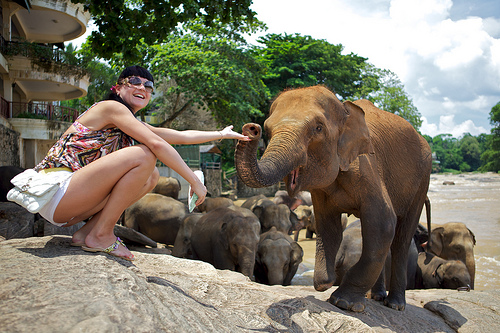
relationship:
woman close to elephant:
[8, 66, 251, 262] [235, 83, 435, 313]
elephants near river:
[121, 176, 478, 290] [414, 170, 497, 291]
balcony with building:
[0, 1, 92, 172] [4, 41, 91, 102]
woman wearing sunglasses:
[8, 66, 251, 262] [120, 76, 154, 90]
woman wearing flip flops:
[8, 66, 251, 262] [70, 239, 135, 259]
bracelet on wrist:
[217, 128, 224, 144] [210, 128, 228, 141]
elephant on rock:
[235, 83, 435, 313] [0, 233, 497, 331]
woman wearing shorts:
[8, 66, 251, 262] [30, 168, 71, 229]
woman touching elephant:
[8, 66, 251, 262] [235, 83, 435, 313]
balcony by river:
[0, 1, 92, 172] [414, 170, 497, 291]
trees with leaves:
[63, 2, 424, 176] [155, 44, 200, 70]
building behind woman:
[4, 41, 91, 102] [8, 66, 251, 262]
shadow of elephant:
[257, 295, 467, 332] [235, 83, 435, 313]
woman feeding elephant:
[8, 66, 251, 262] [235, 83, 435, 313]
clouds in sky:
[415, 17, 493, 100] [243, 0, 499, 140]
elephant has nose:
[235, 83, 435, 313] [234, 122, 307, 187]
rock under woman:
[0, 233, 497, 331] [8, 66, 251, 262]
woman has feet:
[8, 66, 251, 262] [69, 223, 133, 261]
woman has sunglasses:
[8, 66, 251, 262] [120, 76, 154, 90]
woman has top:
[8, 66, 251, 262] [28, 122, 133, 171]